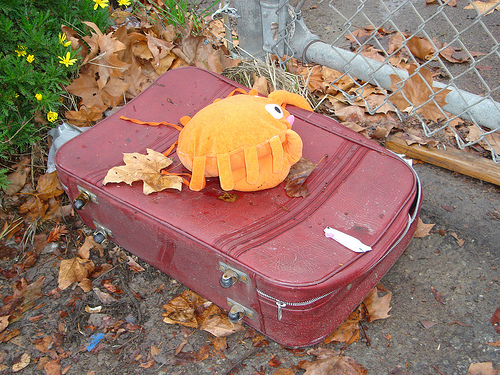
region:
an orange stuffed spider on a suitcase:
[168, 75, 313, 195]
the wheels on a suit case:
[216, 270, 241, 295]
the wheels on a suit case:
[219, 293, 255, 328]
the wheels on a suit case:
[69, 191, 93, 215]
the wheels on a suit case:
[89, 223, 114, 256]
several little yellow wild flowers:
[15, 29, 86, 132]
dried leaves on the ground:
[95, 21, 219, 84]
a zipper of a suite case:
[386, 177, 422, 259]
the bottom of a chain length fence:
[301, 1, 494, 163]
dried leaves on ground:
[324, 75, 427, 137]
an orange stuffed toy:
[161, 86, 316, 191]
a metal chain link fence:
[262, 0, 496, 160]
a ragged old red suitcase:
[55, 71, 422, 338]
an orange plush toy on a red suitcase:
[51, 58, 426, 343]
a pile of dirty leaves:
[0, 208, 236, 367]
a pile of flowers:
[1, 0, 146, 160]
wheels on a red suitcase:
[73, 194, 249, 326]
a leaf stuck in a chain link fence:
[381, 51, 453, 132]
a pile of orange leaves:
[65, 28, 220, 111]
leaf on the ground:
[205, 312, 229, 337]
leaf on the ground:
[52, 255, 90, 287]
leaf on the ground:
[30, 200, 59, 230]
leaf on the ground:
[363, 297, 389, 332]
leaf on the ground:
[405, 220, 450, 248]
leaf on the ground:
[33, 174, 58, 199]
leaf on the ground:
[36, 335, 71, 366]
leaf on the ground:
[36, 347, 73, 373]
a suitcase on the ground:
[0, 3, 495, 363]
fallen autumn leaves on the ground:
[7, 25, 413, 362]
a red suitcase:
[38, 65, 430, 348]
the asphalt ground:
[0, 30, 498, 366]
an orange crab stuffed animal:
[138, 78, 303, 194]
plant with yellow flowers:
[0, 5, 190, 140]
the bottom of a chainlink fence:
[226, 2, 494, 149]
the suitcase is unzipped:
[247, 142, 422, 352]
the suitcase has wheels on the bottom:
[15, 190, 261, 326]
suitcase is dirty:
[46, 60, 430, 344]